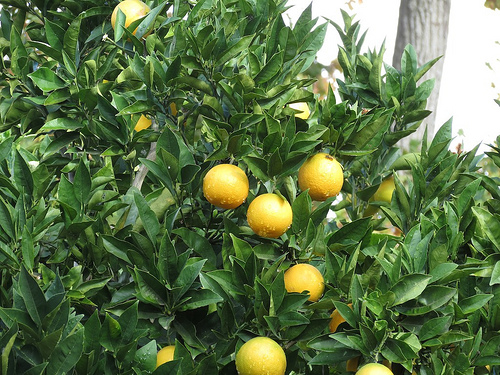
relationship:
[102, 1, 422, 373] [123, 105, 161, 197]
lemons on a branch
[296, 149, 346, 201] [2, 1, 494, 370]
lemon on tree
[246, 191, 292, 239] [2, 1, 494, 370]
lemon on tree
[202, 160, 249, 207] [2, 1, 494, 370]
lemon on tree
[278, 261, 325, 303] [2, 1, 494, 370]
lemon on tree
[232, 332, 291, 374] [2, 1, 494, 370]
lemon on tree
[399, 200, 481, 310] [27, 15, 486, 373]
leaves on tree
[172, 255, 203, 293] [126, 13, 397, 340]
leaf on branch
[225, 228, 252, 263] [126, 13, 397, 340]
leaf on branch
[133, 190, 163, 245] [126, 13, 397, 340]
leaf on branch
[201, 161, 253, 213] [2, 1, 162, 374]
lemons on branches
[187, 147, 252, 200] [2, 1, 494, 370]
lemons in tree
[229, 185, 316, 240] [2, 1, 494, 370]
lemons in tree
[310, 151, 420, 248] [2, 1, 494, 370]
lemons in tree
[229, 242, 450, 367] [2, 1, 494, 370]
lemons in tree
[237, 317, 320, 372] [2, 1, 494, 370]
lemons in tree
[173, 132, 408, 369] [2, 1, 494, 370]
lemons on tree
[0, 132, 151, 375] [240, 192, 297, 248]
tree has lemons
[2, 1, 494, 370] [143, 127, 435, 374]
tree has lemons